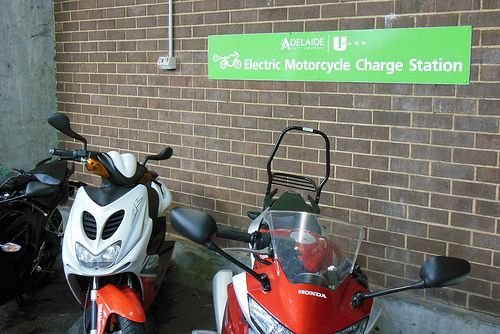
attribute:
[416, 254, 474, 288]
mirrors — rear-view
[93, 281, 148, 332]
cover — red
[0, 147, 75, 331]
motorcycle — white,  red ,  detailing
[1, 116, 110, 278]
motorcycle — black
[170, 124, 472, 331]
motorcycle — red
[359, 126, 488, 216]
wall — red, brick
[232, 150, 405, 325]
bike — red, white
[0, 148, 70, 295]
bike — black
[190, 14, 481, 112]
sign — green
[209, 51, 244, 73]
motorcycle — drawing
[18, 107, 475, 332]
motorcycles — electric 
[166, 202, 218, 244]
mirrors — black 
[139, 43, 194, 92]
outlet — electrical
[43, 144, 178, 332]
motorcycle — white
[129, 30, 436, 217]
wall — brick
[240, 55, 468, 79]
words — electric motorcycle charge station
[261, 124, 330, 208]
rack — black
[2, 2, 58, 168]
wall — solid stone, gray